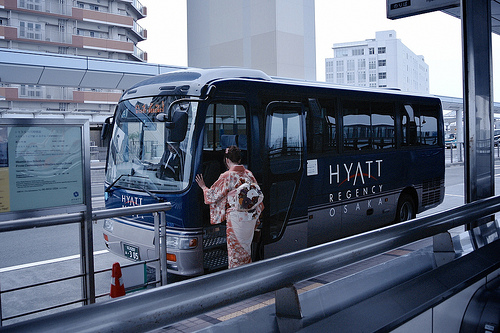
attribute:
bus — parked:
[102, 67, 447, 277]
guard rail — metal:
[4, 195, 497, 330]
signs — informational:
[8, 121, 88, 208]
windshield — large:
[106, 95, 196, 189]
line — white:
[3, 249, 109, 271]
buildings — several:
[2, 0, 430, 170]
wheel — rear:
[395, 196, 420, 223]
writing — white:
[323, 157, 385, 216]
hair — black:
[220, 143, 242, 163]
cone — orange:
[106, 262, 126, 300]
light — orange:
[166, 250, 177, 261]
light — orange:
[102, 233, 109, 242]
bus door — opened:
[194, 92, 261, 237]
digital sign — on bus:
[128, 100, 172, 117]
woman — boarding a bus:
[194, 144, 264, 269]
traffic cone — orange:
[108, 261, 127, 295]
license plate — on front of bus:
[118, 240, 141, 263]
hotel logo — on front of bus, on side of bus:
[326, 158, 386, 218]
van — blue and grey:
[105, 66, 457, 273]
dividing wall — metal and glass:
[0, 1, 471, 330]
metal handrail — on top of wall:
[3, 198, 173, 331]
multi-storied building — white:
[325, 28, 433, 92]